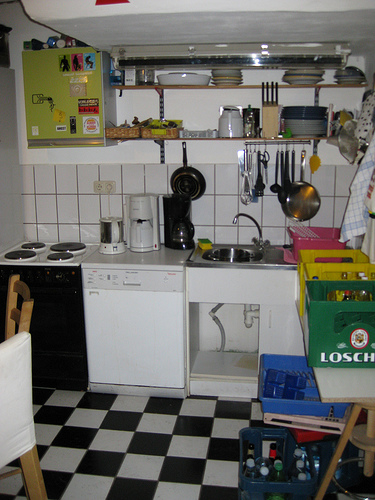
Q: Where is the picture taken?
A: A kitchen.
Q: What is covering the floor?
A: Tile.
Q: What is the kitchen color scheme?
A: Black and white.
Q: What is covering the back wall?
A: Tile.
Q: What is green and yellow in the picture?
A: Plastic tubs.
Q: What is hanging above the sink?
A: Pots and pans.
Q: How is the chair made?
A: Of wood.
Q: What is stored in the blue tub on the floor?
A: Bottles.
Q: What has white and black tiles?
A: The floor.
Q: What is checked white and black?
A: The floor.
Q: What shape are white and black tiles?
A: Square.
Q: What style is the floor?
A: Checkered.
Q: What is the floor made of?
A: Tiles.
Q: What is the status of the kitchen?
A: Organized.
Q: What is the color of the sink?
A: Silver.